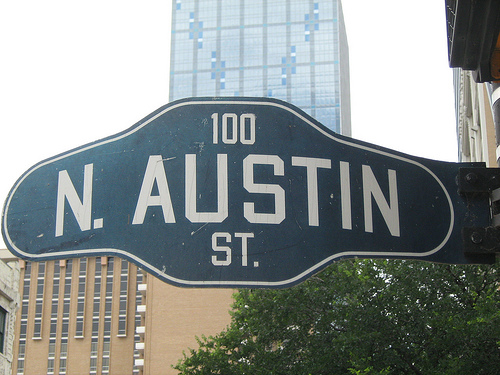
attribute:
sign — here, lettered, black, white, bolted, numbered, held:
[7, 73, 466, 314]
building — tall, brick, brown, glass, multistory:
[162, 5, 392, 184]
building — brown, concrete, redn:
[22, 249, 240, 373]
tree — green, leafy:
[294, 249, 463, 374]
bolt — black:
[457, 168, 485, 288]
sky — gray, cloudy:
[28, 9, 119, 103]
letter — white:
[65, 110, 433, 261]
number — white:
[201, 107, 275, 149]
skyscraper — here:
[148, 6, 361, 190]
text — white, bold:
[146, 139, 431, 230]